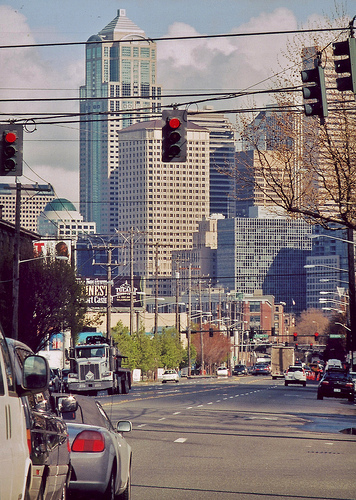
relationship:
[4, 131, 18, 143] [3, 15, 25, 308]
red light on left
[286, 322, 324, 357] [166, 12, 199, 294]
traffic light on right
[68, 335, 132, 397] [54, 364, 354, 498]
truck on street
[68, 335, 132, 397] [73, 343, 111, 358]
truck has window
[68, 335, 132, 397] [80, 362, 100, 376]
truck has grill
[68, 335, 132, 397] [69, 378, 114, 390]
truck has fender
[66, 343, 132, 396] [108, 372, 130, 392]
truck has wheel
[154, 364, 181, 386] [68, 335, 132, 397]
car behind truck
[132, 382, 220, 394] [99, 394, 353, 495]
line on ground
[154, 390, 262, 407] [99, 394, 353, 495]
line on ground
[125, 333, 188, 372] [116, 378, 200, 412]
trees on road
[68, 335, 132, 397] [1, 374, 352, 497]
truck on road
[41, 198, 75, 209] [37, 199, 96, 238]
dome on building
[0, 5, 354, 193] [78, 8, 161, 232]
clouds behind building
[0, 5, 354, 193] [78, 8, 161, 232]
clouds above building